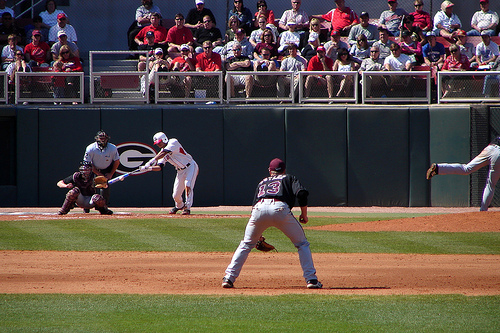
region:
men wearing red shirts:
[133, 15, 199, 43]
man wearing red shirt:
[313, 4, 357, 33]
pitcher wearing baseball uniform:
[223, 131, 333, 310]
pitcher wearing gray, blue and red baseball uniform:
[228, 134, 342, 313]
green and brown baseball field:
[351, 214, 486, 310]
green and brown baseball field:
[21, 221, 211, 313]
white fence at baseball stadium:
[361, 65, 496, 111]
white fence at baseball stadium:
[18, 63, 238, 111]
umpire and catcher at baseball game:
[26, 125, 138, 230]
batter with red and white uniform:
[132, 124, 208, 230]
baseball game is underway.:
[14, 13, 491, 319]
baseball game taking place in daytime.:
[10, 26, 492, 318]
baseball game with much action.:
[11, 14, 493, 321]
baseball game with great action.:
[1, 3, 493, 320]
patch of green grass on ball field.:
[6, 288, 476, 328]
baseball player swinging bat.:
[111, 128, 213, 215]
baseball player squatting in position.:
[56, 160, 114, 213]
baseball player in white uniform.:
[124, 119, 210, 215]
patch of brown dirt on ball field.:
[1, 245, 210, 292]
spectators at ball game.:
[0, 3, 488, 81]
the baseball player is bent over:
[221, 155, 323, 281]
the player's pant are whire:
[222, 198, 324, 289]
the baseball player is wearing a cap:
[267, 156, 289, 173]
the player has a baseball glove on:
[250, 237, 273, 253]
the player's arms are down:
[249, 173, 313, 257]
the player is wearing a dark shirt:
[252, 171, 307, 208]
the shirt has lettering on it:
[255, 175, 288, 199]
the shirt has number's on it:
[256, 180, 281, 197]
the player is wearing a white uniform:
[148, 130, 198, 213]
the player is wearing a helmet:
[153, 131, 168, 146]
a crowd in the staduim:
[138, 3, 490, 97]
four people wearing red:
[142, 12, 220, 68]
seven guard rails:
[15, 68, 499, 102]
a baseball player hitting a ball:
[109, 129, 199, 214]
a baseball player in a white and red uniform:
[147, 129, 199, 214]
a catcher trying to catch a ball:
[56, 159, 111, 215]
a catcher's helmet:
[77, 159, 94, 180]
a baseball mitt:
[254, 234, 276, 256]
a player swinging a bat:
[107, 128, 197, 211]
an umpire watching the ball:
[82, 130, 119, 215]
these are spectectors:
[131, 4, 453, 68]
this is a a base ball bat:
[105, 162, 142, 188]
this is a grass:
[158, 295, 412, 329]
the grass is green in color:
[156, 296, 356, 321]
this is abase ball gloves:
[91, 181, 111, 191]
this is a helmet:
[144, 128, 176, 145]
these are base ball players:
[46, 111, 213, 214]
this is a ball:
[116, 172, 128, 184]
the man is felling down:
[422, 131, 499, 214]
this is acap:
[266, 155, 284, 176]